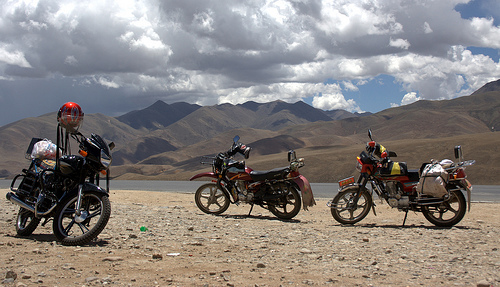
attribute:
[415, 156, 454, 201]
bag — white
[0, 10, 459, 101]
sky — dark, gray, cloudy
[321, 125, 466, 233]
bike — motor bike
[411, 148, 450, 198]
bag — white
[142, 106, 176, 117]
darkness — from clouds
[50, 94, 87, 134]
helmet — shiny, red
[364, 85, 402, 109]
space — clear, Blue, open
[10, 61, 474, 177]
mountainous area — rural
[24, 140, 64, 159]
bag — plastic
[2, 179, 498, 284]
shore — rocky, dirt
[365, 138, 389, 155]
accents — red, yellow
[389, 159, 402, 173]
paint — yellow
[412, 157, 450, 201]
bag — white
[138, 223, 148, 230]
bottle — green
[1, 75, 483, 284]
area — remote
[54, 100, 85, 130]
helmet — red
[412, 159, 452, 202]
storage pack — white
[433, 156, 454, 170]
storage pack — white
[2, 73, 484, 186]
mountain — sunlit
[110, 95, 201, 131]
area — shady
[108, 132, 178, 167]
area — shady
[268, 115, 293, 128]
area — shady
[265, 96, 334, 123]
area — shady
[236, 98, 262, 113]
area — shady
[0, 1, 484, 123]
sky — mostly cloudy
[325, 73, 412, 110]
patch — blue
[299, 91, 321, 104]
patch — blue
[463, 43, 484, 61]
patch — blue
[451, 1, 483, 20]
patch — blue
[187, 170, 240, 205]
front fender — red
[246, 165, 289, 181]
seat — black, vinyl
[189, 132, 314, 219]
motorcycle — black, red